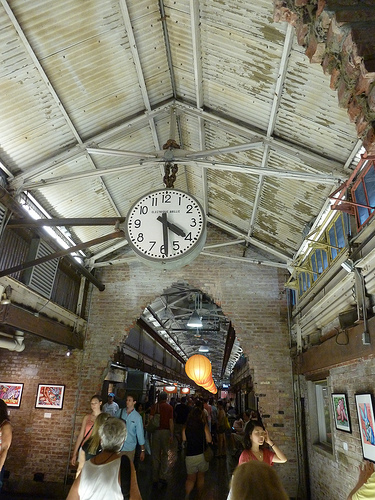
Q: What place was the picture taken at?
A: It was taken at the station.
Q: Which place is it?
A: It is a station.